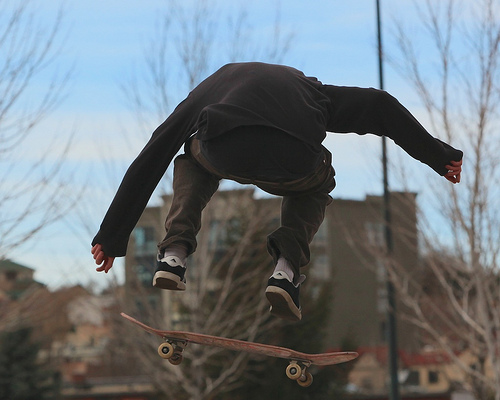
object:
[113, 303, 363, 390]
skateboard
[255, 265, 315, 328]
shoes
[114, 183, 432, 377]
building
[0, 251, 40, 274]
roof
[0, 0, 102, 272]
trees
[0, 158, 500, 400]
background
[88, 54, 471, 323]
skateboarder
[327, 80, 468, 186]
arm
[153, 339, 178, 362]
wheels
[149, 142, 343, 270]
pants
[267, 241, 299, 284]
socks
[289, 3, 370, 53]
sky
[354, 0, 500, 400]
tree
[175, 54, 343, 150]
top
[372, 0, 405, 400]
pole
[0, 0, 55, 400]
corner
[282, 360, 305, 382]
wheels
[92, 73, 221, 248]
sleeves